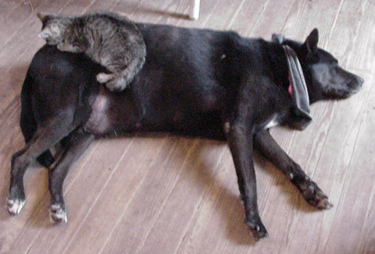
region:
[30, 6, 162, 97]
a grey cat with stripes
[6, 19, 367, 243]
a large black dog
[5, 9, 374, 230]
a cat sleeps on a dog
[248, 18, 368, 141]
a dog wearing a bandana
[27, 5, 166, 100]
a sleepy grey cat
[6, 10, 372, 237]
a cat and dog lie on a wooden floor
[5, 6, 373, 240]
a cat and dog being friends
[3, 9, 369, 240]
a sleepy black dog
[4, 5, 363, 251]
a dog and cat being lazy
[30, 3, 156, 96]
a cat using a dog as a pillow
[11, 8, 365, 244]
the cat is laying on the dog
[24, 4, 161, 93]
the cat is black and gray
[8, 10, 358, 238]
the dog is black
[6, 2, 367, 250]
the dog is laying on the floor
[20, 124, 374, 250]
the floor is brown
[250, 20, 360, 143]
the dog has something around its neck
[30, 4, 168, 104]
the kitten is cute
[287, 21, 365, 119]
the dog's ear is sticking up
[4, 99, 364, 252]
the floor is wooden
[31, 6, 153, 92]
the kitten is curled up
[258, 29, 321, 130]
the dog is wearing a bandana on his neck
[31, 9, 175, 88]
the kitten is laying on top of the dog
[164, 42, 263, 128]
the dog is black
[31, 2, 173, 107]
the kitten is stripped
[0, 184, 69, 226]
the dogs paws are white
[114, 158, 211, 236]
the floor is wooden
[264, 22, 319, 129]
the bandana is grey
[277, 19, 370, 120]
the dog is asleep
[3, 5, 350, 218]
the dog doesnt seem to mind the kitty laying on him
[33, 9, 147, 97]
the kitten is asleep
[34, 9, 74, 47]
the head of a cat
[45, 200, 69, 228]
the paw of a dog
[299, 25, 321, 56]
the ear of a dog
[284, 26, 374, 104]
the head of a dog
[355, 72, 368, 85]
the nose of a dog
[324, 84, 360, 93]
the mouth of a dog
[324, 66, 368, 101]
the snout of a dog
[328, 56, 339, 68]
the eye of a dog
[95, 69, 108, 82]
the paw of a cat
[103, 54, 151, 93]
the tail of a cat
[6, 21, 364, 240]
a black dog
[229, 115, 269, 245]
a black dog's leg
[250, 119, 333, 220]
a black dog's leg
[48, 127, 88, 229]
a black dog's leg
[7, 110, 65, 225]
a black dog's leg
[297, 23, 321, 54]
a black dog's ear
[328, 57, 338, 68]
a black dog's eye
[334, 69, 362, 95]
a black dog's mouth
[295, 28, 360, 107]
a black dog's head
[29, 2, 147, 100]
a cat on top of a dog